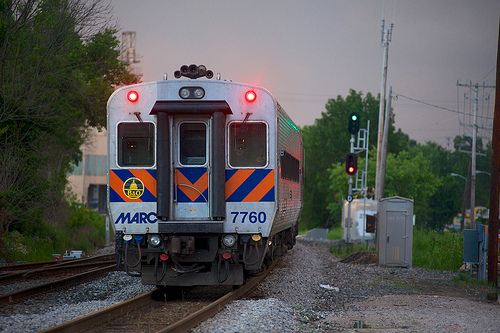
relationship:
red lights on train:
[127, 88, 139, 104] [104, 76, 286, 272]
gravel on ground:
[38, 292, 67, 321] [291, 290, 374, 329]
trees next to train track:
[10, 49, 63, 245] [35, 255, 284, 331]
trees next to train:
[10, 49, 63, 245] [104, 76, 286, 272]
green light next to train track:
[350, 113, 359, 122] [35, 255, 284, 331]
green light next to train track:
[350, 113, 359, 122] [65, 294, 235, 333]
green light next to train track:
[350, 111, 359, 128] [35, 255, 284, 331]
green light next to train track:
[350, 111, 359, 128] [65, 294, 235, 333]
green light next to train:
[350, 111, 359, 128] [104, 76, 286, 272]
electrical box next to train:
[455, 219, 484, 280] [104, 76, 286, 272]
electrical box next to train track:
[455, 219, 484, 280] [35, 255, 284, 331]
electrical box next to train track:
[455, 219, 484, 280] [65, 294, 235, 333]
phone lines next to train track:
[460, 58, 496, 219] [35, 255, 284, 331]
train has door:
[104, 76, 286, 272] [162, 108, 219, 224]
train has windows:
[104, 76, 286, 272] [228, 121, 272, 171]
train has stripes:
[104, 76, 286, 272] [174, 169, 282, 205]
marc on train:
[111, 210, 160, 233] [104, 76, 286, 272]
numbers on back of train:
[230, 210, 271, 227] [104, 76, 286, 272]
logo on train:
[122, 176, 149, 201] [104, 76, 286, 272]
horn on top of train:
[170, 57, 218, 80] [104, 76, 286, 272]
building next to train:
[67, 109, 106, 210] [104, 76, 286, 272]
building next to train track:
[67, 109, 106, 210] [35, 255, 284, 331]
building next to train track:
[67, 109, 106, 210] [65, 294, 235, 333]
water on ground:
[329, 316, 399, 331] [291, 290, 374, 329]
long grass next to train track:
[418, 231, 468, 273] [35, 255, 284, 331]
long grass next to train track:
[418, 231, 468, 273] [65, 294, 235, 333]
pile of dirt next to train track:
[346, 243, 379, 264] [35, 255, 284, 331]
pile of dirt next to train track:
[346, 243, 379, 264] [65, 294, 235, 333]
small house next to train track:
[379, 195, 417, 271] [35, 255, 284, 331]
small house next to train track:
[379, 195, 417, 271] [65, 294, 235, 333]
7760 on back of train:
[230, 210, 271, 227] [104, 76, 286, 272]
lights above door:
[178, 85, 212, 102] [162, 108, 219, 224]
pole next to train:
[379, 21, 401, 204] [104, 76, 286, 272]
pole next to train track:
[379, 21, 401, 204] [35, 255, 284, 331]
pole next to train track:
[379, 21, 401, 204] [65, 294, 235, 333]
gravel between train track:
[38, 292, 67, 321] [65, 294, 235, 333]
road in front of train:
[308, 220, 332, 246] [104, 76, 286, 272]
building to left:
[67, 109, 106, 210] [7, 132, 40, 217]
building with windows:
[67, 109, 106, 210] [228, 121, 272, 171]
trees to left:
[10, 49, 63, 245] [7, 132, 40, 217]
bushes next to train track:
[7, 197, 95, 250] [35, 255, 284, 331]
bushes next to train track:
[7, 197, 95, 250] [65, 294, 235, 333]